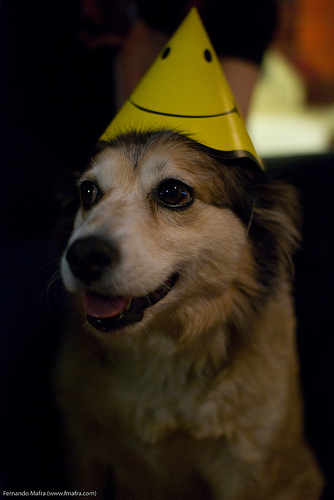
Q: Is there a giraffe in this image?
A: No, there are no giraffes.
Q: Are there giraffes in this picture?
A: No, there are no giraffes.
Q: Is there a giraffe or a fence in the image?
A: No, there are no giraffes or fences.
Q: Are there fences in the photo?
A: No, there are no fences.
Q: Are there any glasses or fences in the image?
A: No, there are no fences or glasses.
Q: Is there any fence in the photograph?
A: No, there are no fences.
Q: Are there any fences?
A: No, there are no fences.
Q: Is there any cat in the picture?
A: No, there are no cats.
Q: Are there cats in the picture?
A: No, there are no cats.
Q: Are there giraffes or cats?
A: No, there are no cats or giraffes.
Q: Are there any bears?
A: No, there are no bears.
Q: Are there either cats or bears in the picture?
A: No, there are no bears or cats.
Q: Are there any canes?
A: No, there are no canes.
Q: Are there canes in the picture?
A: No, there are no canes.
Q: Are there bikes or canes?
A: No, there are no canes or bikes.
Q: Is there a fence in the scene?
A: No, there are no fences.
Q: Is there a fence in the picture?
A: No, there are no fences.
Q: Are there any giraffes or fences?
A: No, there are no fences or giraffes.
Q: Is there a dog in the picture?
A: Yes, there is a dog.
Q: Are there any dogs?
A: Yes, there is a dog.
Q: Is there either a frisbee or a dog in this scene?
A: Yes, there is a dog.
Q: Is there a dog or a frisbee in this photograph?
A: Yes, there is a dog.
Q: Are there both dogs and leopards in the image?
A: No, there is a dog but no leopards.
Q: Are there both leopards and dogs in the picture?
A: No, there is a dog but no leopards.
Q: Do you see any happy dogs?
A: Yes, there is a happy dog.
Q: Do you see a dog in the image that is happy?
A: Yes, there is a dog that is happy.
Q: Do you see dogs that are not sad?
A: Yes, there is a happy dog.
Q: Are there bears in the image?
A: No, there are no bears.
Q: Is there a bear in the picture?
A: No, there are no bears.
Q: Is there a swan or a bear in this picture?
A: No, there are no bears or swans.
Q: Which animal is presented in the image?
A: The animal is a dog.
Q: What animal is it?
A: The animal is a dog.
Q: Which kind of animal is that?
A: This is a dog.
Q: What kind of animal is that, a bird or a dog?
A: This is a dog.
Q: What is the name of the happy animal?
A: The animal is a dog.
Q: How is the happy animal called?
A: The animal is a dog.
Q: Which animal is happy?
A: The animal is a dog.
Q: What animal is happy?
A: The animal is a dog.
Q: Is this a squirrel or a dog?
A: This is a dog.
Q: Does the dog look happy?
A: Yes, the dog is happy.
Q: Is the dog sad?
A: No, the dog is happy.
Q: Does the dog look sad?
A: No, the dog is happy.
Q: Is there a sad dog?
A: No, there is a dog but it is happy.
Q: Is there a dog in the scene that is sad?
A: No, there is a dog but it is happy.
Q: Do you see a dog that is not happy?
A: No, there is a dog but it is happy.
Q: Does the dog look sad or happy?
A: The dog is happy.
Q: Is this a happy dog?
A: Yes, this is a happy dog.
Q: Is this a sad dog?
A: No, this is a happy dog.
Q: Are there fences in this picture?
A: No, there are no fences.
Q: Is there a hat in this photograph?
A: Yes, there is a hat.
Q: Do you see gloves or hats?
A: Yes, there is a hat.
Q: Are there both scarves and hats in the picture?
A: No, there is a hat but no scarves.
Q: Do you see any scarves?
A: No, there are no scarves.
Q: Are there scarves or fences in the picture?
A: No, there are no scarves or fences.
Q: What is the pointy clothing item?
A: The clothing item is a hat.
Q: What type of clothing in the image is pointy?
A: The clothing is a hat.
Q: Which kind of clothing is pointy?
A: The clothing is a hat.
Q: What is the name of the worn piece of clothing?
A: The clothing item is a hat.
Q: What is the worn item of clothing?
A: The clothing item is a hat.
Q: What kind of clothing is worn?
A: The clothing is a hat.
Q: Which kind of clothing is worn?
A: The clothing is a hat.